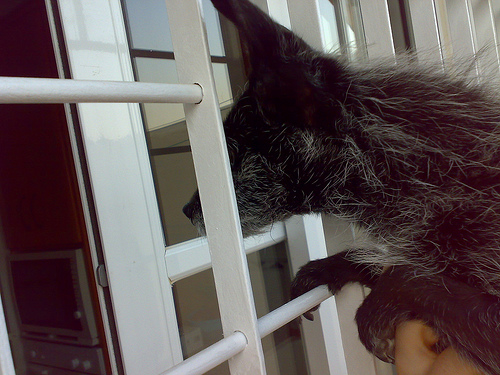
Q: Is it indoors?
A: Yes, it is indoors.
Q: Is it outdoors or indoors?
A: It is indoors.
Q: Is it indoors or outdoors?
A: It is indoors.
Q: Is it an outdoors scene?
A: No, it is indoors.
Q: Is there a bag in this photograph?
A: No, there are no bags.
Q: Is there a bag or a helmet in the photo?
A: No, there are no bags or helmets.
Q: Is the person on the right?
A: Yes, the person is on the right of the image.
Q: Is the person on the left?
A: No, the person is on the right of the image.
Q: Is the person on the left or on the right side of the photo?
A: The person is on the right of the image.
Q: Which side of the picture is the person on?
A: The person is on the right of the image.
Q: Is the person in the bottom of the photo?
A: Yes, the person is in the bottom of the image.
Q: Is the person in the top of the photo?
A: No, the person is in the bottom of the image.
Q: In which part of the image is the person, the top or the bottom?
A: The person is in the bottom of the image.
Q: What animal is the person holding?
A: The person is holding the dog.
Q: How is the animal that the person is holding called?
A: The animal is a dog.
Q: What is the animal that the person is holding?
A: The animal is a dog.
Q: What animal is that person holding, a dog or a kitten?
A: The person is holding a dog.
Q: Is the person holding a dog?
A: Yes, the person is holding a dog.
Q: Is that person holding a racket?
A: No, the person is holding a dog.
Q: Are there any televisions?
A: Yes, there is a television.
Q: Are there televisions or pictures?
A: Yes, there is a television.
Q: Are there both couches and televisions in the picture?
A: No, there is a television but no couches.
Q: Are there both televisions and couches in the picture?
A: No, there is a television but no couches.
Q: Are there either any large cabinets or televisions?
A: Yes, there is a large television.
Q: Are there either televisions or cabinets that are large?
A: Yes, the television is large.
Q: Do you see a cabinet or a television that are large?
A: Yes, the television is large.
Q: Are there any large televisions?
A: Yes, there is a large television.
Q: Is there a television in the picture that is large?
A: Yes, there is a television that is large.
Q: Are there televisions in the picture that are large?
A: Yes, there is a television that is large.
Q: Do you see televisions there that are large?
A: Yes, there is a television that is large.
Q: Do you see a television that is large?
A: Yes, there is a television that is large.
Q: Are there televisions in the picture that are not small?
A: Yes, there is a large television.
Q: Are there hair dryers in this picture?
A: No, there are no hair dryers.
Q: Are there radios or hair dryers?
A: No, there are no hair dryers or radios.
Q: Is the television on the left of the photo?
A: Yes, the television is on the left of the image.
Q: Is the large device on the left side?
A: Yes, the television is on the left of the image.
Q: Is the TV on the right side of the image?
A: No, the TV is on the left of the image.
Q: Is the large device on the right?
A: No, the TV is on the left of the image.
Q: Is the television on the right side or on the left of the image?
A: The television is on the left of the image.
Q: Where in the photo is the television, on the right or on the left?
A: The television is on the left of the image.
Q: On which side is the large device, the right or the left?
A: The television is on the left of the image.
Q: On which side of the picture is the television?
A: The television is on the left of the image.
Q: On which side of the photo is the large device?
A: The television is on the left of the image.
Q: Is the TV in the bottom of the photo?
A: Yes, the TV is in the bottom of the image.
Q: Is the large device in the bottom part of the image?
A: Yes, the TV is in the bottom of the image.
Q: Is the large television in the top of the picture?
A: No, the television is in the bottom of the image.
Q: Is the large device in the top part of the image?
A: No, the television is in the bottom of the image.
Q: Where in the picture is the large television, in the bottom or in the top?
A: The television is in the bottom of the image.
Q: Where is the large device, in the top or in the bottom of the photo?
A: The television is in the bottom of the image.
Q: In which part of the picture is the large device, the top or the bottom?
A: The television is in the bottom of the image.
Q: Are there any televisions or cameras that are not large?
A: No, there is a television but it is large.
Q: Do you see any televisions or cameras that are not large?
A: No, there is a television but it is large.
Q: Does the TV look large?
A: Yes, the TV is large.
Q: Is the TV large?
A: Yes, the TV is large.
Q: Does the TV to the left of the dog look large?
A: Yes, the TV is large.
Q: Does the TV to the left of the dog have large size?
A: Yes, the TV is large.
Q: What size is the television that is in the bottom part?
A: The television is large.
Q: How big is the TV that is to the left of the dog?
A: The TV is large.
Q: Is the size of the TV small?
A: No, the TV is large.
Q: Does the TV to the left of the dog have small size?
A: No, the television is large.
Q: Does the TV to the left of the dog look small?
A: No, the television is large.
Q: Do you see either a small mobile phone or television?
A: No, there is a television but it is large.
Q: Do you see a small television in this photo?
A: No, there is a television but it is large.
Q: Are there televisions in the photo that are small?
A: No, there is a television but it is large.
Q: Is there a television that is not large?
A: No, there is a television but it is large.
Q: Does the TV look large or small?
A: The TV is large.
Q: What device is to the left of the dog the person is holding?
A: The device is a television.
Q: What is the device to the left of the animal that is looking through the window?
A: The device is a television.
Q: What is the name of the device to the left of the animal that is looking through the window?
A: The device is a television.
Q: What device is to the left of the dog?
A: The device is a television.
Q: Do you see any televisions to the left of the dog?
A: Yes, there is a television to the left of the dog.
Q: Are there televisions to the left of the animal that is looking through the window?
A: Yes, there is a television to the left of the dog.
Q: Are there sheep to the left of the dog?
A: No, there is a television to the left of the dog.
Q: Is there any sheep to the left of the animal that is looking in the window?
A: No, there is a television to the left of the dog.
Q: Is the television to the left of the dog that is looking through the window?
A: Yes, the television is to the left of the dog.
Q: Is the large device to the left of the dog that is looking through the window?
A: Yes, the television is to the left of the dog.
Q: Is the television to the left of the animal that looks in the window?
A: Yes, the television is to the left of the dog.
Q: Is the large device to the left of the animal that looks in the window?
A: Yes, the television is to the left of the dog.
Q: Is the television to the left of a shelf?
A: No, the television is to the left of the dog.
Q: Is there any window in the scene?
A: Yes, there is a window.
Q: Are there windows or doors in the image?
A: Yes, there is a window.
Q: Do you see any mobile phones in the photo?
A: No, there are no mobile phones.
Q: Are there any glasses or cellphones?
A: No, there are no cellphones or glasses.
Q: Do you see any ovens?
A: Yes, there is an oven.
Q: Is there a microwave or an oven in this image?
A: Yes, there is an oven.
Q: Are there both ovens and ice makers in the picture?
A: No, there is an oven but no ice makers.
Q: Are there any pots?
A: No, there are no pots.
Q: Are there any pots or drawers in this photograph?
A: No, there are no pots or drawers.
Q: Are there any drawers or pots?
A: No, there are no pots or drawers.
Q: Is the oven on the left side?
A: Yes, the oven is on the left of the image.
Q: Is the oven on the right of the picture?
A: No, the oven is on the left of the image.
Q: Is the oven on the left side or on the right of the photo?
A: The oven is on the left of the image.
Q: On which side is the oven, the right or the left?
A: The oven is on the left of the image.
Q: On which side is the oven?
A: The oven is on the left of the image.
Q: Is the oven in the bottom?
A: Yes, the oven is in the bottom of the image.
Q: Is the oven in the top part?
A: No, the oven is in the bottom of the image.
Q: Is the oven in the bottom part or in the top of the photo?
A: The oven is in the bottom of the image.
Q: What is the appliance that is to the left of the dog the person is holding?
A: The appliance is an oven.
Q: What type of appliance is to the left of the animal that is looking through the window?
A: The appliance is an oven.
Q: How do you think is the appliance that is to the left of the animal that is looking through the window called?
A: The appliance is an oven.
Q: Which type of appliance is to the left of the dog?
A: The appliance is an oven.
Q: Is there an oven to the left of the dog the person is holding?
A: Yes, there is an oven to the left of the dog.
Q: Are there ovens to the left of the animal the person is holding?
A: Yes, there is an oven to the left of the dog.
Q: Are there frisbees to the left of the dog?
A: No, there is an oven to the left of the dog.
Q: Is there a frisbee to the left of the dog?
A: No, there is an oven to the left of the dog.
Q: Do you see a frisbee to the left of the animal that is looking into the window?
A: No, there is an oven to the left of the dog.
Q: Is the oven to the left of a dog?
A: Yes, the oven is to the left of a dog.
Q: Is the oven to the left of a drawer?
A: No, the oven is to the left of a dog.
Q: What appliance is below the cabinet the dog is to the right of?
A: The appliance is an oven.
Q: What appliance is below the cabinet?
A: The appliance is an oven.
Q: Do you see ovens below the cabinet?
A: Yes, there is an oven below the cabinet.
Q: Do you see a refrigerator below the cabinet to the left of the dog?
A: No, there is an oven below the cabinet.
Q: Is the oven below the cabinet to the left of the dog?
A: Yes, the oven is below the cabinet.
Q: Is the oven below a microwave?
A: No, the oven is below the cabinet.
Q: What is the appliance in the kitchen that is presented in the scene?
A: The appliance is an oven.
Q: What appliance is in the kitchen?
A: The appliance is an oven.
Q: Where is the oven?
A: The oven is in the kitchen.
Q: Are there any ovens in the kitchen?
A: Yes, there is an oven in the kitchen.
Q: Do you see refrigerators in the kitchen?
A: No, there is an oven in the kitchen.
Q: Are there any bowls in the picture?
A: No, there are no bowls.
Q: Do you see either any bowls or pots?
A: No, there are no bowls or pots.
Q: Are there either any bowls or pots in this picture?
A: No, there are no bowls or pots.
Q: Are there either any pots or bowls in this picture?
A: No, there are no bowls or pots.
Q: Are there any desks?
A: No, there are no desks.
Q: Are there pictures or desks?
A: No, there are no desks or pictures.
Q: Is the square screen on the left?
A: Yes, the screen is on the left of the image.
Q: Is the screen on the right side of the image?
A: No, the screen is on the left of the image.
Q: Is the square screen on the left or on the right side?
A: The screen is on the left of the image.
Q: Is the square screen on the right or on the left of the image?
A: The screen is on the left of the image.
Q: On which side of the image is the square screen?
A: The screen is on the left of the image.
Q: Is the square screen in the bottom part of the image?
A: Yes, the screen is in the bottom of the image.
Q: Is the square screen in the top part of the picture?
A: No, the screen is in the bottom of the image.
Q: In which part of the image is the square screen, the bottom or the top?
A: The screen is in the bottom of the image.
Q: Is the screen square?
A: Yes, the screen is square.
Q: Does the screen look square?
A: Yes, the screen is square.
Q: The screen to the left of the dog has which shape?
A: The screen is square.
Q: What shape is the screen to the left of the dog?
A: The screen is square.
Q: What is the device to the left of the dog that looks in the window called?
A: The device is a screen.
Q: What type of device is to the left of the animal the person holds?
A: The device is a screen.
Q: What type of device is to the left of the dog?
A: The device is a screen.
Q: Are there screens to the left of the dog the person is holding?
A: Yes, there is a screen to the left of the dog.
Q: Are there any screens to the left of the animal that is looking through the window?
A: Yes, there is a screen to the left of the dog.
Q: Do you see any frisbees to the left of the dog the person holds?
A: No, there is a screen to the left of the dog.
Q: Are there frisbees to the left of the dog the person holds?
A: No, there is a screen to the left of the dog.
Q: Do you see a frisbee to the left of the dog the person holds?
A: No, there is a screen to the left of the dog.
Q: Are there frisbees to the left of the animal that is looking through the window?
A: No, there is a screen to the left of the dog.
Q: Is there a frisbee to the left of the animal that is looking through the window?
A: No, there is a screen to the left of the dog.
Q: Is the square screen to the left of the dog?
A: Yes, the screen is to the left of the dog.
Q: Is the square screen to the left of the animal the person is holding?
A: Yes, the screen is to the left of the dog.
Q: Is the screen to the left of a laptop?
A: No, the screen is to the left of the dog.